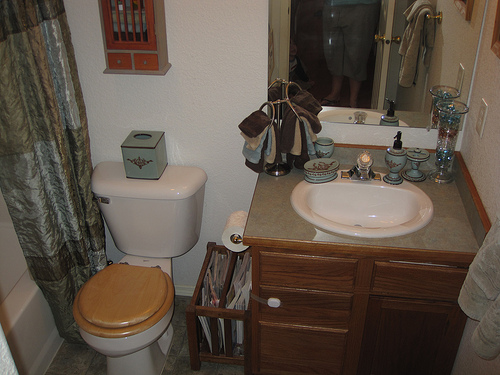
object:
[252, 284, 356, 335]
drawer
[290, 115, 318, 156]
sock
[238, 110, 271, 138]
sock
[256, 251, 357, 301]
drawer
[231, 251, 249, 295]
newspapers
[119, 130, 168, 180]
tissue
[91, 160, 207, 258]
tank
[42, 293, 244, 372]
ground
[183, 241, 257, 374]
magazine rack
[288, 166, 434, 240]
sink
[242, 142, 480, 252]
top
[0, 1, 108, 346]
curtain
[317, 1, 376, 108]
reflection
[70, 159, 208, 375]
toilet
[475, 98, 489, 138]
electrical plug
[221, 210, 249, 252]
toilet paper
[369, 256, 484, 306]
drawer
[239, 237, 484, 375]
cabinet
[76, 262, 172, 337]
seat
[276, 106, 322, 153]
towel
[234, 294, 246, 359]
magazines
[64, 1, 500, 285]
wall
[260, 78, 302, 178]
holder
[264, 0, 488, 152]
mirror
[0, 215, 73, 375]
bathtub